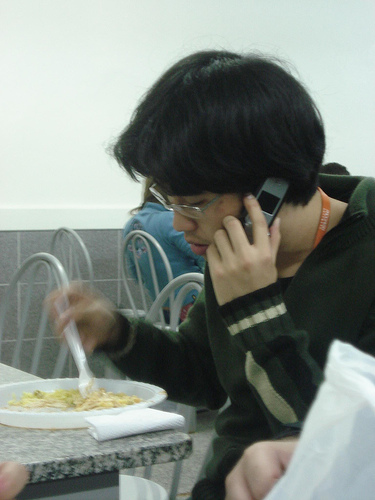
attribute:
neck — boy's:
[266, 184, 345, 256]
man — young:
[100, 37, 352, 402]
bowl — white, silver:
[2, 347, 177, 446]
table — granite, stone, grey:
[3, 363, 186, 487]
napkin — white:
[71, 366, 214, 451]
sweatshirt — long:
[110, 223, 373, 438]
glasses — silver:
[121, 172, 222, 238]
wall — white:
[8, 4, 136, 202]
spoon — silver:
[52, 313, 113, 385]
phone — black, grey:
[205, 134, 312, 294]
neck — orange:
[260, 141, 366, 317]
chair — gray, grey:
[1, 224, 93, 369]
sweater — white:
[217, 240, 319, 411]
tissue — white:
[79, 384, 174, 425]